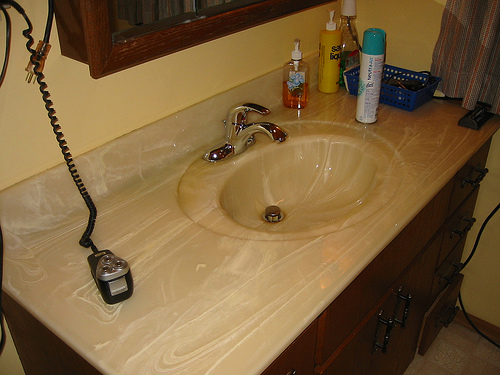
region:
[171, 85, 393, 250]
sink on the counter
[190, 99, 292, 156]
faucet of the sink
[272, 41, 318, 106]
soap in the bottle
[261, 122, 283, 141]
the faucet is silver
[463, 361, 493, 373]
the floor is tile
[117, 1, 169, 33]
bottom of the mirror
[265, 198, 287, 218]
drain of the sink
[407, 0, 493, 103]
curtain on the side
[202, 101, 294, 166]
Chrome finished faucet of a sink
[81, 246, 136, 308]
Black and silver electric shaver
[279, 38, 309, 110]
Bottle of hand wash by a sink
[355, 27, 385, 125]
Can of air freshener in a bathroom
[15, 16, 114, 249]
Coiled cord for an electric shaver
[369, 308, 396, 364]
Dark silver handle for a wooden cupboard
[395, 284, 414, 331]
Dark silver handle for a wooden cupboard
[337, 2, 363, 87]
Bottle of mouthwash in the background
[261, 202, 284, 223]
The drain of a sink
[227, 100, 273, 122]
The handle of a chrome sink faucet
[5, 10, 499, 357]
clean marbelized bathroom counter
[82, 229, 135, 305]
corded electric men's shaver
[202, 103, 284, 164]
Metal faucet fixture of sink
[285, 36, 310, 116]
bottle of orange hand soap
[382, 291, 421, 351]
metal hardware to bathroom cabinet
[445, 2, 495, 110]
red and grey striped curtain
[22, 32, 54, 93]
electrical chord hanging from wall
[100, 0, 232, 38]
portion of medicine cabinet with mirror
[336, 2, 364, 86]
bottle of mouthwash on bathroom counter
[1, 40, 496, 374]
an off-white bathroom counter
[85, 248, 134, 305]
a black and gray electric razor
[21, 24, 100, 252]
a spiraled black cord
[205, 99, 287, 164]
the faucet on a bathroom sink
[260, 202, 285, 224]
the drain of a bathroom sink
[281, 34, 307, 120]
a bottle of hand soap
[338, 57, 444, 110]
a blue basket on a counter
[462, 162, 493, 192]
the metal handle of a drawer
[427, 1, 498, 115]
a striped curtain next to a bathroom counter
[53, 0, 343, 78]
a brown wood cabinet above a sink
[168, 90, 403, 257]
this is a sink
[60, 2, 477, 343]
this is a bathroom counter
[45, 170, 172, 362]
this is an electric razer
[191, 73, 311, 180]
this is a faucet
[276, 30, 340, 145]
this is a bottle of hand soap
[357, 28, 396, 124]
this is an aerosol can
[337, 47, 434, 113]
blue basket on counter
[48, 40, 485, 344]
bathroom counter is light brown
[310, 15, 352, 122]
yellow bottle on counter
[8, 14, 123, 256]
black chord to razer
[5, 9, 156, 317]
shaver on the counter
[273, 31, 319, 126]
bottle on the counter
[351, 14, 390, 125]
can on the counter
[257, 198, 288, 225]
stopper in the sink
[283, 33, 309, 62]
pump on the bottle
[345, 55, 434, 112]
basket on the counter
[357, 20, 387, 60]
blue top on can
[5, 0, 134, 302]
electric razor plugged into wall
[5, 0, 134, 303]
silver and black electric razor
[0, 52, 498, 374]
beige colored marble countertop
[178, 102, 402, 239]
silver faucet behind sink basin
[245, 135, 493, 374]
dark brown wood cabinetry with metal handles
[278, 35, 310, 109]
orange soap inside soap dispenser